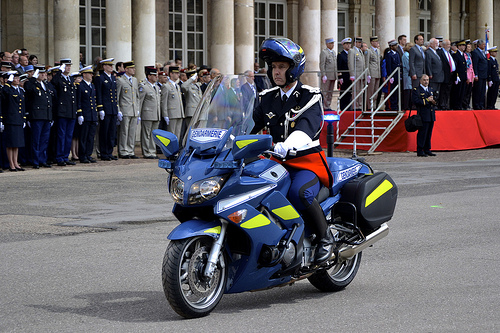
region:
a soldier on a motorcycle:
[142, 33, 408, 316]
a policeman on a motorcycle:
[146, 31, 409, 306]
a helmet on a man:
[256, 31, 308, 95]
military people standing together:
[0, 56, 202, 170]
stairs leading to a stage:
[336, 66, 408, 154]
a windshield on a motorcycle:
[187, 76, 257, 146]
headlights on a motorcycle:
[167, 171, 230, 205]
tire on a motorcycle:
[165, 215, 227, 317]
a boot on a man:
[308, 203, 336, 261]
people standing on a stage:
[319, 28, 499, 158]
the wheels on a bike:
[153, 212, 258, 306]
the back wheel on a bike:
[304, 208, 381, 292]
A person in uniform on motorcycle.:
[251, 31, 335, 191]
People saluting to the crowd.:
[24, 48, 101, 165]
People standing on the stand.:
[358, 38, 481, 105]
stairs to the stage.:
[341, 55, 409, 159]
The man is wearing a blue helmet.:
[256, 33, 315, 73]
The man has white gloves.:
[276, 132, 305, 152]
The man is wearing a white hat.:
[93, 49, 118, 66]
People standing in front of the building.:
[13, 39, 225, 140]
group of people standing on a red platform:
[321, 34, 498, 110]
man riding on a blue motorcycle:
[152, 35, 398, 317]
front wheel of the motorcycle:
[161, 234, 233, 319]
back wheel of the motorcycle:
[305, 216, 362, 291]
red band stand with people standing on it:
[318, 109, 498, 151]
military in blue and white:
[1, 57, 125, 164]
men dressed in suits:
[117, 61, 213, 160]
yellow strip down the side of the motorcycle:
[203, 179, 392, 234]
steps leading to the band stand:
[334, 109, 403, 154]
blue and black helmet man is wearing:
[266, 34, 306, 89]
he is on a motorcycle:
[121, 28, 431, 332]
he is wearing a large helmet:
[143, 15, 417, 332]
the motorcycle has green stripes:
[117, 7, 465, 331]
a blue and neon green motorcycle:
[120, 26, 471, 332]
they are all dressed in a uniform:
[6, 41, 238, 170]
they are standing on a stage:
[311, 19, 498, 170]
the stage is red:
[314, 80, 499, 167]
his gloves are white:
[261, 119, 332, 164]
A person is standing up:
[117, 59, 139, 161]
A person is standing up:
[71, 62, 101, 162]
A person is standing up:
[54, 52, 79, 162]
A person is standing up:
[28, 63, 51, 163]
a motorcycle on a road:
[144, 70, 395, 316]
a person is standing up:
[415, 73, 440, 157]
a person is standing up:
[3, 65, 30, 172]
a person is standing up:
[24, 60, 56, 169]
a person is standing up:
[45, 59, 79, 164]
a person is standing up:
[74, 60, 102, 161]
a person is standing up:
[111, 55, 138, 159]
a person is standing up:
[141, 61, 157, 157]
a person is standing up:
[318, 33, 341, 103]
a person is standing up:
[348, 34, 366, 106]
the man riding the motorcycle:
[248, 34, 335, 265]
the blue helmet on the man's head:
[258, 34, 306, 84]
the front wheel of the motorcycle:
[161, 236, 227, 319]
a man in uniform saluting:
[25, 64, 55, 170]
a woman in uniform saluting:
[1, 69, 28, 172]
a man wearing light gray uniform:
[116, 60, 140, 160]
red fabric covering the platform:
[317, 107, 498, 150]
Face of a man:
[270, 61, 288, 85]